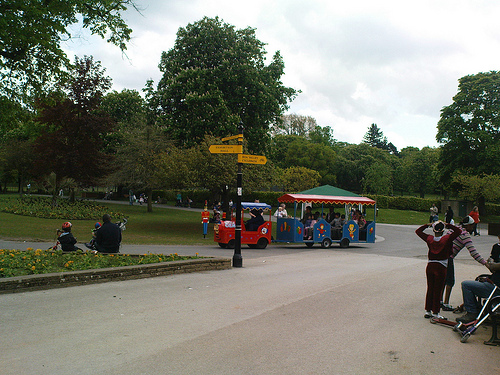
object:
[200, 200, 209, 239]
soldier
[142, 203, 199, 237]
grass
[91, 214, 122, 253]
people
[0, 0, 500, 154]
sky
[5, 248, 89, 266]
flowers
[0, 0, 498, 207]
green trees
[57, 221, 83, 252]
people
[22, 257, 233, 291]
curb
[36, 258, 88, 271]
grass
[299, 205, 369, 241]
people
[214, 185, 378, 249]
train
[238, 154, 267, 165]
sign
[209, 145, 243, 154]
sign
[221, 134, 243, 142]
signs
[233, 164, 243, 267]
black pole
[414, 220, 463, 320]
man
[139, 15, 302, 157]
tree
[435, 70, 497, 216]
tree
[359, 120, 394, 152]
tree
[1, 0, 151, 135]
tree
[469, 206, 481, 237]
person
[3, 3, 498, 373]
park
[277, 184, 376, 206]
colored awning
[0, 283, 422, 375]
sidewalk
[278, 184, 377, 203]
roof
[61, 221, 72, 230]
helmet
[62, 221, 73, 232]
head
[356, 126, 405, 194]
tree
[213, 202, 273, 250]
train engine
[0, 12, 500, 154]
cloud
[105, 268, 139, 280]
brick.